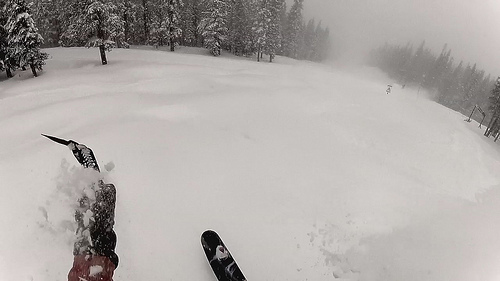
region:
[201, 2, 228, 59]
a pine tree covered in snow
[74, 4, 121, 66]
a pine tree covered in snow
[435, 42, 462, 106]
a pine tree covered in snow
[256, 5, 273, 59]
a pine tree covered in snow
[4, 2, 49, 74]
a pine tree covered in snow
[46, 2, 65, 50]
a pine tree covered in snow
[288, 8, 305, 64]
a pine tree covered in snow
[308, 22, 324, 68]
a pine tree covered in snow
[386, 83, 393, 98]
a sign in the middle of snow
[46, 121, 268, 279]
a person skiing in the snow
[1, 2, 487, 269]
Snowy and windy mountain.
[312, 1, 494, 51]
Foggy sky in the background.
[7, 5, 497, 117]
Pine trees covered with snow.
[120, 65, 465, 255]
Huge bump of snow.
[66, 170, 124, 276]
Person's foot falling on the snow.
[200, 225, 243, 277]
Right ski of a falling person.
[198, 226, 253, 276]
Ski is black.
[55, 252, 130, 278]
Skier wearing red snow pants.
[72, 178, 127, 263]
Skier wearing black snow boot.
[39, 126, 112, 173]
End of the ski is twisted.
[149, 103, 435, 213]
thick snow on the ground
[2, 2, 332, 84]
snow on the trees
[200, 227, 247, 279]
the front of ski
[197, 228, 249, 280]
a black ski on the snow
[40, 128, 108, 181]
a tool in a person's hand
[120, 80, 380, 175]
white snow covering the ground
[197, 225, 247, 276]
the upper part of a snow ski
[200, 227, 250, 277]
a black snow ski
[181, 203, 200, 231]
part f a grpound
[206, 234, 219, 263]
part of a board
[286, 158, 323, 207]
part ofo a snow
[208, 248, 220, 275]
part of a board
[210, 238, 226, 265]
part of a board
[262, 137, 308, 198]
[art fo a snw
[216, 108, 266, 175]
part of a ground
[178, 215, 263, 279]
the view of a ski from a skier's point of view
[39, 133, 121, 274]
a skier's glove holding the handle of a ski pole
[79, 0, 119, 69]
a conifer tree in the snow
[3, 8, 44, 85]
a conifer tree in the snow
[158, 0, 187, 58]
a conifer tree in the snow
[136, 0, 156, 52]
a conifer tree in the snow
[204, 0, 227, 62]
a conifer tree in the snow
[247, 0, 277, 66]
conifer trees in the snow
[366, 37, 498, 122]
several conifer trees in the snow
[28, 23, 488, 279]
snow on the ground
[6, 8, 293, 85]
snow on the trees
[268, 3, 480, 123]
fog in the air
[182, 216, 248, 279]
front of a ski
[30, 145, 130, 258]
snow in the air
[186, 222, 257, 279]
the ski is black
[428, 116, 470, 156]
track in the snow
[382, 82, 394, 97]
sign in the distance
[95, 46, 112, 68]
trunk on the tree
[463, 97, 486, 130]
structure in the distance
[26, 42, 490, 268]
snow on the ground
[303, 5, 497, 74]
the sky is discolored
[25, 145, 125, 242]
snow in the air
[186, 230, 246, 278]
tip of a ski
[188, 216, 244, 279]
the ski is black